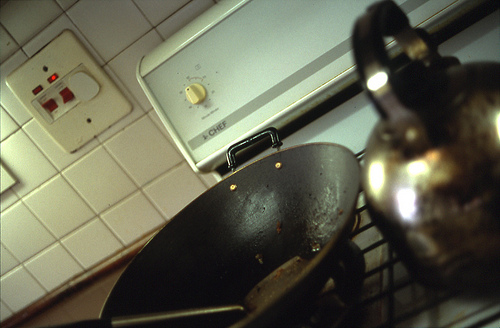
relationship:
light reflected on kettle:
[365, 70, 389, 93] [348, 0, 499, 296]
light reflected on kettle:
[366, 156, 430, 225] [348, 0, 499, 296]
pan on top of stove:
[99, 127, 362, 328] [136, 0, 497, 328]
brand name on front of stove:
[200, 119, 229, 141] [136, 0, 497, 328]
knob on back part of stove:
[182, 82, 206, 105] [136, 0, 497, 328]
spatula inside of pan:
[48, 255, 309, 327] [99, 127, 362, 328]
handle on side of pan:
[225, 126, 284, 168] [99, 127, 362, 328]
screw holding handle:
[274, 163, 283, 169] [225, 126, 284, 168]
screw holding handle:
[226, 180, 237, 191] [225, 126, 284, 168]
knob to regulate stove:
[182, 82, 206, 105] [136, 0, 497, 328]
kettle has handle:
[348, 0, 499, 296] [351, 0, 430, 119]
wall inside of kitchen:
[1, 0, 227, 327] [1, 0, 499, 327]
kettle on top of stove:
[348, 0, 499, 296] [136, 0, 497, 328]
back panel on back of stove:
[135, 1, 499, 177] [136, 0, 497, 328]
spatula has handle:
[48, 255, 309, 327] [40, 313, 112, 327]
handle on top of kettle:
[351, 0, 430, 119] [348, 0, 499, 296]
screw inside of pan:
[274, 163, 283, 169] [99, 127, 362, 328]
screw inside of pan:
[226, 180, 237, 191] [99, 127, 362, 328]